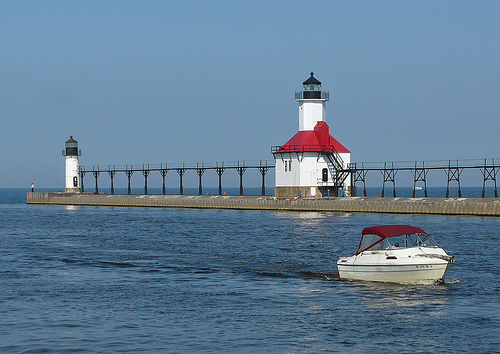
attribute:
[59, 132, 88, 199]
lighthouse — white, black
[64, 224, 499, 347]
water — calm, blue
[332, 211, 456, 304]
boat — white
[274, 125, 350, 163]
roof — red